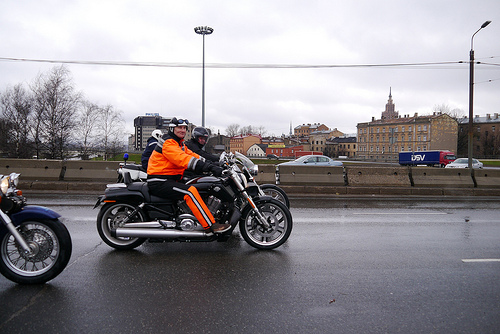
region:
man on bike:
[65, 126, 305, 264]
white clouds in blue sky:
[297, 41, 332, 75]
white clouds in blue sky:
[367, 19, 421, 50]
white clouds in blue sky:
[217, 60, 254, 91]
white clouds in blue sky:
[274, 39, 296, 79]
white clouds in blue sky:
[120, 32, 168, 79]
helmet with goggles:
[166, 110, 193, 130]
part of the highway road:
[388, 253, 415, 276]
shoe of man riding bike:
[204, 221, 236, 238]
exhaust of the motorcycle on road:
[114, 229, 201, 246]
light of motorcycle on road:
[247, 163, 265, 180]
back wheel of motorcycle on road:
[92, 195, 148, 256]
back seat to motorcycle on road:
[100, 180, 146, 205]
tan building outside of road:
[347, 81, 462, 163]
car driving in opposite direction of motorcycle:
[268, 151, 350, 176]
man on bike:
[81, 105, 308, 262]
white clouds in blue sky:
[345, 100, 371, 120]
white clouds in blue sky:
[331, 43, 388, 85]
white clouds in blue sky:
[271, 93, 305, 125]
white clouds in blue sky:
[282, 49, 303, 74]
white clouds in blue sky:
[131, 46, 166, 67]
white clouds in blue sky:
[355, 32, 405, 62]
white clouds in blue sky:
[298, 36, 339, 66]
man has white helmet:
[138, 110, 188, 145]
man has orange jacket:
[154, 142, 201, 188]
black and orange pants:
[154, 185, 220, 242]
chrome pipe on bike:
[107, 206, 227, 253]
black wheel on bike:
[219, 198, 296, 249]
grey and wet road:
[297, 258, 388, 320]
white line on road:
[465, 240, 498, 268]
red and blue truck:
[392, 138, 452, 170]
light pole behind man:
[182, 28, 211, 128]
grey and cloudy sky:
[310, 28, 374, 93]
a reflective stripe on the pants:
[170, 183, 213, 227]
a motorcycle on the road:
[93, 153, 293, 250]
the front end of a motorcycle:
[0, 172, 68, 280]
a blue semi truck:
[393, 148, 456, 166]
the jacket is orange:
[141, 137, 206, 184]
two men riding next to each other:
[95, 111, 290, 250]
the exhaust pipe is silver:
[113, 227, 207, 238]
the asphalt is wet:
[0, 200, 496, 324]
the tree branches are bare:
[0, 68, 125, 153]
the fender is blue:
[11, 200, 62, 219]